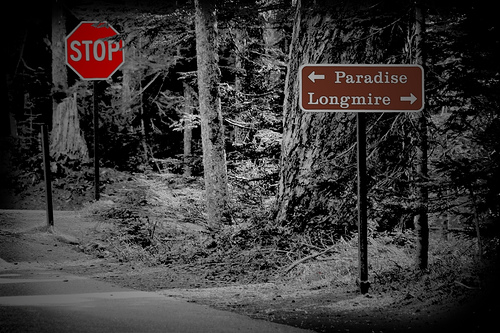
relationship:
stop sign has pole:
[60, 20, 127, 83] [89, 80, 105, 206]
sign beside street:
[296, 62, 424, 116] [2, 199, 290, 332]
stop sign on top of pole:
[60, 20, 127, 83] [89, 80, 105, 206]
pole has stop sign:
[89, 80, 105, 206] [60, 20, 127, 83]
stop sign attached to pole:
[60, 20, 127, 83] [89, 80, 105, 206]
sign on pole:
[296, 62, 424, 116] [89, 80, 105, 206]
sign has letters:
[296, 62, 424, 116] [68, 38, 127, 63]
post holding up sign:
[352, 114, 375, 269] [296, 62, 424, 116]